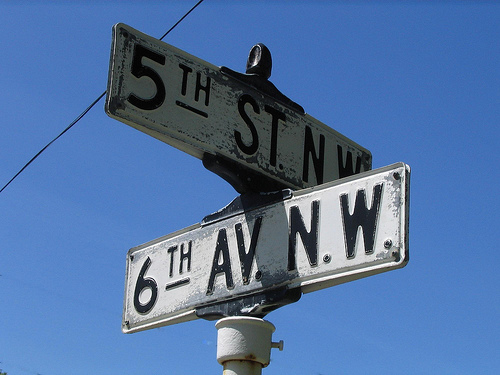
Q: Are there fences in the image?
A: No, there are no fences.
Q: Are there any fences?
A: No, there are no fences.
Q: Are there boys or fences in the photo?
A: No, there are no fences or boys.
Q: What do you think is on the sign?
A: The cap is on the sign.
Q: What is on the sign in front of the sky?
A: The cap is on the sign.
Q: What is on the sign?
A: The cap is on the sign.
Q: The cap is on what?
A: The cap is on the sign.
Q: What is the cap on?
A: The cap is on the sign.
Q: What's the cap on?
A: The cap is on the sign.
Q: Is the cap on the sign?
A: Yes, the cap is on the sign.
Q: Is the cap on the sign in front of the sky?
A: Yes, the cap is on the sign.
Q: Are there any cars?
A: No, there are no cars.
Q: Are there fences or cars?
A: No, there are no cars or fences.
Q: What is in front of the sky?
A: The sign is in front of the sky.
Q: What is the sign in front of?
A: The sign is in front of the sky.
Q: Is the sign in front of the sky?
A: Yes, the sign is in front of the sky.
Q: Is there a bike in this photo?
A: No, there are no bikes.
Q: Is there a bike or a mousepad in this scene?
A: No, there are no bikes or mouse pads.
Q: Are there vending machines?
A: No, there are no vending machines.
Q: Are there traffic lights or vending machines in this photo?
A: No, there are no vending machines or traffic lights.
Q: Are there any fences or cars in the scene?
A: No, there are no cars or fences.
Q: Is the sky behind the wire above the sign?
A: Yes, the sky is behind the wire.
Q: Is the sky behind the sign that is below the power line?
A: Yes, the sky is behind the sign.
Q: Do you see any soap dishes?
A: No, there are no soap dishes.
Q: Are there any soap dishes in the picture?
A: No, there are no soap dishes.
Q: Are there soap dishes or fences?
A: No, there are no soap dishes or fences.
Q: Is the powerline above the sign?
A: Yes, the powerline is above the sign.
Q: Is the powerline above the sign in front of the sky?
A: Yes, the powerline is above the sign.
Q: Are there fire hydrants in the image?
A: No, there are no fire hydrants.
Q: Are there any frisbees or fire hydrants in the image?
A: No, there are no fire hydrants or frisbees.